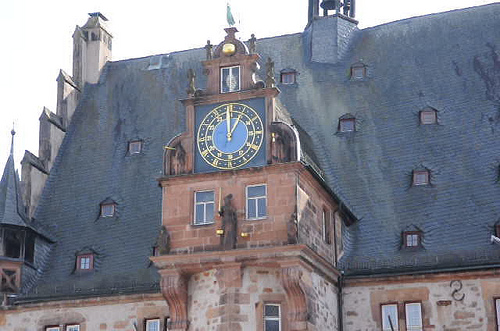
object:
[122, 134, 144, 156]
small window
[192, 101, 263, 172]
clock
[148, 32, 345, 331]
clock tower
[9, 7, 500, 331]
building